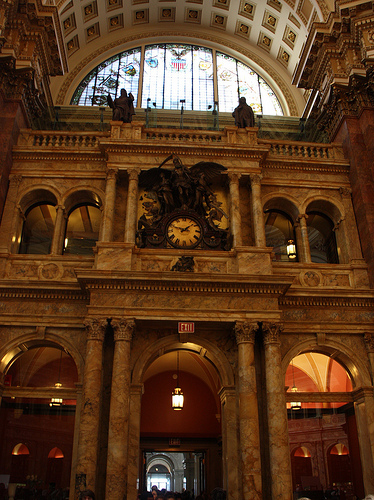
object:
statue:
[106, 87, 138, 125]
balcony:
[10, 121, 347, 165]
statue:
[232, 97, 257, 129]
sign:
[177, 319, 196, 334]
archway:
[128, 331, 241, 500]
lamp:
[168, 384, 182, 411]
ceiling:
[141, 349, 223, 407]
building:
[0, 0, 374, 496]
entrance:
[74, 269, 294, 500]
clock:
[165, 215, 204, 251]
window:
[53, 22, 308, 122]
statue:
[134, 154, 234, 252]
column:
[235, 324, 260, 500]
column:
[106, 318, 132, 500]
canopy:
[282, 337, 372, 410]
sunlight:
[148, 478, 168, 489]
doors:
[143, 451, 191, 494]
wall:
[327, 103, 374, 277]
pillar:
[229, 170, 247, 254]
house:
[2, 2, 373, 499]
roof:
[3, 2, 372, 87]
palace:
[2, 2, 372, 500]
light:
[169, 346, 189, 414]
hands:
[171, 222, 194, 235]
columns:
[82, 321, 287, 500]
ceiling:
[41, 0, 327, 87]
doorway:
[144, 453, 177, 496]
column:
[84, 316, 104, 497]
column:
[265, 320, 285, 496]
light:
[131, 47, 246, 110]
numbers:
[167, 216, 200, 249]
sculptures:
[102, 86, 256, 130]